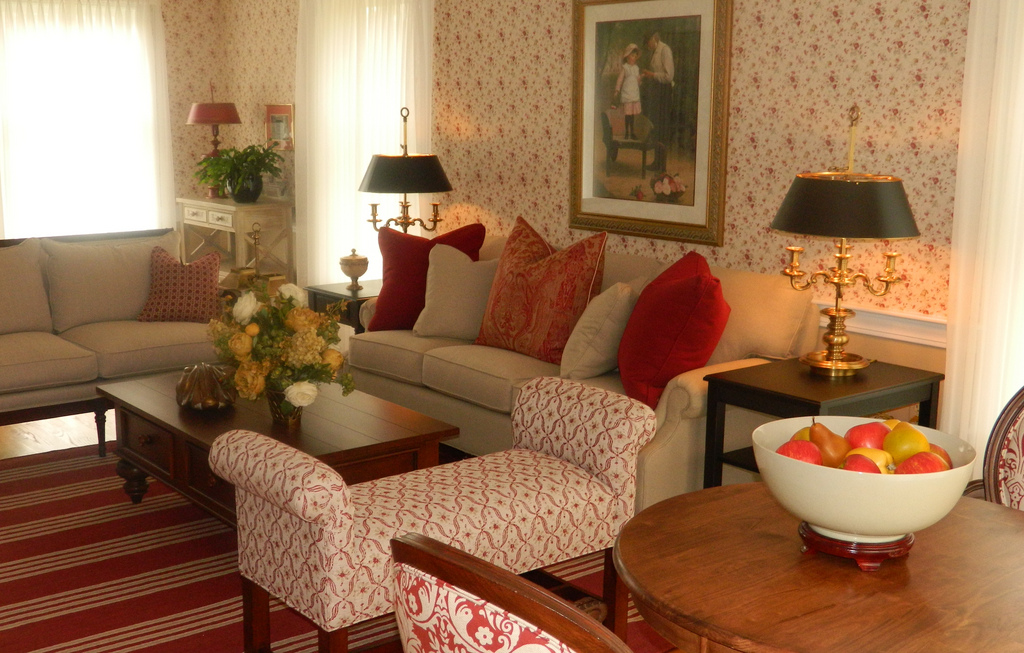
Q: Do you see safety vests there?
A: No, there are no safety vests.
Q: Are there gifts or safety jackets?
A: No, there are no safety jackets or gifts.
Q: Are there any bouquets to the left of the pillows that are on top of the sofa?
A: Yes, there is a bouquet to the left of the pillows.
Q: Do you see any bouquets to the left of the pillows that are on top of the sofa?
A: Yes, there is a bouquet to the left of the pillows.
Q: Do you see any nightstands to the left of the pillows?
A: No, there is a bouquet to the left of the pillows.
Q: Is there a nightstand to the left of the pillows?
A: No, there is a bouquet to the left of the pillows.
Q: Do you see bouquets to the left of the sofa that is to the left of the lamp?
A: Yes, there is a bouquet to the left of the sofa.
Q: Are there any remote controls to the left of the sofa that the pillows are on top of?
A: No, there is a bouquet to the left of the sofa.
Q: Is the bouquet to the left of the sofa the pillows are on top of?
A: Yes, the bouquet is to the left of the sofa.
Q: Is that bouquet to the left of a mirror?
A: No, the bouquet is to the left of the sofa.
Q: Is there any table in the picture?
A: Yes, there is a table.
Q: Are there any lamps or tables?
A: Yes, there is a table.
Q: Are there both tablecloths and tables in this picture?
A: No, there is a table but no tablecloths.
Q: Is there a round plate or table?
A: Yes, there is a round table.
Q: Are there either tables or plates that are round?
A: Yes, the table is round.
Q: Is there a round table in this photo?
A: Yes, there is a round table.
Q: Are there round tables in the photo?
A: Yes, there is a round table.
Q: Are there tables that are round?
A: Yes, there is a table that is round.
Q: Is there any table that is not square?
A: Yes, there is a round table.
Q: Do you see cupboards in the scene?
A: No, there are no cupboards.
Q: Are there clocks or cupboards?
A: No, there are no cupboards or clocks.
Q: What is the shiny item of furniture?
A: The piece of furniture is a table.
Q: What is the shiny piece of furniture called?
A: The piece of furniture is a table.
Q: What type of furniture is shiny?
A: The furniture is a table.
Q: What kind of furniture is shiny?
A: The furniture is a table.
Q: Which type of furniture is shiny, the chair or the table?
A: The table is shiny.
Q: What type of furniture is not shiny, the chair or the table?
A: The chair is not shiny.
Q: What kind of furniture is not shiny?
A: The furniture is a chair.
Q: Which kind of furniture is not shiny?
A: The furniture is a chair.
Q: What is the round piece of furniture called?
A: The piece of furniture is a table.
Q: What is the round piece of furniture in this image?
A: The piece of furniture is a table.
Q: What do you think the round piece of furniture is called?
A: The piece of furniture is a table.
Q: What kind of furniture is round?
A: The furniture is a table.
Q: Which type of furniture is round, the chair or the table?
A: The table is round.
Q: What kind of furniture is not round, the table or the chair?
A: The chair is not round.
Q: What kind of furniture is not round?
A: The furniture is a chair.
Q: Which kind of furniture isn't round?
A: The furniture is a chair.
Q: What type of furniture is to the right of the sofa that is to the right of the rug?
A: The piece of furniture is a table.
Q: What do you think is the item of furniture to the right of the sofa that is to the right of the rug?
A: The piece of furniture is a table.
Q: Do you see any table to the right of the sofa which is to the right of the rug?
A: Yes, there is a table to the right of the sofa.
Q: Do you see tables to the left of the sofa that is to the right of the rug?
A: No, the table is to the right of the sofa.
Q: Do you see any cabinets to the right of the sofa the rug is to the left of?
A: No, there is a table to the right of the sofa.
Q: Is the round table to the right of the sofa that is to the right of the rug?
A: Yes, the table is to the right of the sofa.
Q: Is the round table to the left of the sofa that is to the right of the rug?
A: No, the table is to the right of the sofa.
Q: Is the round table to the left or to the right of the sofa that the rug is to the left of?
A: The table is to the right of the sofa.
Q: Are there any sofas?
A: Yes, there is a sofa.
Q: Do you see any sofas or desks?
A: Yes, there is a sofa.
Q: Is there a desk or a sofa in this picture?
A: Yes, there is a sofa.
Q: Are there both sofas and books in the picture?
A: No, there is a sofa but no books.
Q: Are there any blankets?
A: No, there are no blankets.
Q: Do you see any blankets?
A: No, there are no blankets.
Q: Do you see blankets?
A: No, there are no blankets.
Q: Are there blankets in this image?
A: No, there are no blankets.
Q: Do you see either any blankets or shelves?
A: No, there are no blankets or shelves.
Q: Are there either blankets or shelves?
A: No, there are no blankets or shelves.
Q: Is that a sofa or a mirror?
A: That is a sofa.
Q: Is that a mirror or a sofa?
A: That is a sofa.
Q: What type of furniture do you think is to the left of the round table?
A: The piece of furniture is a sofa.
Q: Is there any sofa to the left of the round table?
A: Yes, there is a sofa to the left of the table.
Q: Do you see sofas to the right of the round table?
A: No, the sofa is to the left of the table.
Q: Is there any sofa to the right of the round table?
A: No, the sofa is to the left of the table.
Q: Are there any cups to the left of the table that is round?
A: No, there is a sofa to the left of the table.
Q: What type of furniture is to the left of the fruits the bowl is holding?
A: The piece of furniture is a sofa.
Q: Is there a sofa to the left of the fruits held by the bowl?
A: Yes, there is a sofa to the left of the fruits.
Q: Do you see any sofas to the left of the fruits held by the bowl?
A: Yes, there is a sofa to the left of the fruits.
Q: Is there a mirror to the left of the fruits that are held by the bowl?
A: No, there is a sofa to the left of the fruits.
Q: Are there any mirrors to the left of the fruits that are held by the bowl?
A: No, there is a sofa to the left of the fruits.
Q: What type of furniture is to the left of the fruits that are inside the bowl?
A: The piece of furniture is a sofa.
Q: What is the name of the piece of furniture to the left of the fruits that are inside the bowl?
A: The piece of furniture is a sofa.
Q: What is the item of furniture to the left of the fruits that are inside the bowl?
A: The piece of furniture is a sofa.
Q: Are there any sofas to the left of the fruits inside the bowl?
A: Yes, there is a sofa to the left of the fruits.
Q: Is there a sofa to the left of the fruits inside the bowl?
A: Yes, there is a sofa to the left of the fruits.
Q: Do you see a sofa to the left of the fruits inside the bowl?
A: Yes, there is a sofa to the left of the fruits.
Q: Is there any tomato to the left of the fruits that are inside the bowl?
A: No, there is a sofa to the left of the fruits.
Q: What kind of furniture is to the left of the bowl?
A: The piece of furniture is a sofa.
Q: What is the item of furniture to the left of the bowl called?
A: The piece of furniture is a sofa.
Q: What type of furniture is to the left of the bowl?
A: The piece of furniture is a sofa.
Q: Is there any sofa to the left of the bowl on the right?
A: Yes, there is a sofa to the left of the bowl.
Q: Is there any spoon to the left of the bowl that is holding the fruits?
A: No, there is a sofa to the left of the bowl.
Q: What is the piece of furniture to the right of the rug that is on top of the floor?
A: The piece of furniture is a sofa.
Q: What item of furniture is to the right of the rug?
A: The piece of furniture is a sofa.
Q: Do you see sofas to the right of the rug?
A: Yes, there is a sofa to the right of the rug.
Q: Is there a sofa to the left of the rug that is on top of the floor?
A: No, the sofa is to the right of the rug.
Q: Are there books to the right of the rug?
A: No, there is a sofa to the right of the rug.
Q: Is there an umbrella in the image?
A: No, there are no umbrellas.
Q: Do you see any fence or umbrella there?
A: No, there are no umbrellas or fences.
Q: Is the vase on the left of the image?
A: Yes, the vase is on the left of the image.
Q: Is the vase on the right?
A: No, the vase is on the left of the image.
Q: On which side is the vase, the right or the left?
A: The vase is on the left of the image.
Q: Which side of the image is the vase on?
A: The vase is on the left of the image.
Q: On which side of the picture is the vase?
A: The vase is on the left of the image.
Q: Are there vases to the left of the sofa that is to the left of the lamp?
A: Yes, there is a vase to the left of the sofa.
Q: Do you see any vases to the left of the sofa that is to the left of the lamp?
A: Yes, there is a vase to the left of the sofa.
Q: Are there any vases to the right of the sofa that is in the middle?
A: No, the vase is to the left of the sofa.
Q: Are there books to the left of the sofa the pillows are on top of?
A: No, there is a vase to the left of the sofa.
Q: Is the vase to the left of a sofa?
A: Yes, the vase is to the left of a sofa.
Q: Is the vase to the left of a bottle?
A: No, the vase is to the left of a sofa.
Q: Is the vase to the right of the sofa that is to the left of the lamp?
A: No, the vase is to the left of the sofa.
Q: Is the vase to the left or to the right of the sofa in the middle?
A: The vase is to the left of the sofa.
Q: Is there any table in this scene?
A: Yes, there is a table.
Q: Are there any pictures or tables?
A: Yes, there is a table.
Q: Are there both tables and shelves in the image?
A: No, there is a table but no shelves.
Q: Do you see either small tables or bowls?
A: Yes, there is a small table.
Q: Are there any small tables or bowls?
A: Yes, there is a small table.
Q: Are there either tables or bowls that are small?
A: Yes, the table is small.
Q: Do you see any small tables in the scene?
A: Yes, there is a small table.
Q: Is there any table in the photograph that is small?
A: Yes, there is a table that is small.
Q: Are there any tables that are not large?
A: Yes, there is a small table.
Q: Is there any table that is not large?
A: Yes, there is a small table.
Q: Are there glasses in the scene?
A: No, there are no glasses.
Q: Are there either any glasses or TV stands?
A: No, there are no glasses or TV stands.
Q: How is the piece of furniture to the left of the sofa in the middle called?
A: The piece of furniture is a table.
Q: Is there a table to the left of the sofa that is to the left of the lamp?
A: Yes, there is a table to the left of the sofa.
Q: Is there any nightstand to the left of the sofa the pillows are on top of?
A: No, there is a table to the left of the sofa.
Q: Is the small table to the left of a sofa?
A: Yes, the table is to the left of a sofa.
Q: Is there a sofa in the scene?
A: Yes, there is a sofa.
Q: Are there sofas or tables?
A: Yes, there is a sofa.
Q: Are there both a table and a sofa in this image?
A: Yes, there are both a sofa and a table.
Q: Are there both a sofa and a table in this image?
A: Yes, there are both a sofa and a table.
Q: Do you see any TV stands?
A: No, there are no TV stands.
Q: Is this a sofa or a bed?
A: This is a sofa.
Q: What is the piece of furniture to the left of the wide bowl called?
A: The piece of furniture is a sofa.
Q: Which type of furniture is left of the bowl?
A: The piece of furniture is a sofa.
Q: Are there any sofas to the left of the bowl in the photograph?
A: Yes, there is a sofa to the left of the bowl.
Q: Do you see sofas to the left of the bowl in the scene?
A: Yes, there is a sofa to the left of the bowl.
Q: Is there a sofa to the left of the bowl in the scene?
A: Yes, there is a sofa to the left of the bowl.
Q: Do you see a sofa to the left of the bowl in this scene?
A: Yes, there is a sofa to the left of the bowl.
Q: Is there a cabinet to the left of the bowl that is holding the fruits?
A: No, there is a sofa to the left of the bowl.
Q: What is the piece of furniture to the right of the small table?
A: The piece of furniture is a sofa.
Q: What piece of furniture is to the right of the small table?
A: The piece of furniture is a sofa.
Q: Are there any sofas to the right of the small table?
A: Yes, there is a sofa to the right of the table.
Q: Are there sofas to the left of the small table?
A: No, the sofa is to the right of the table.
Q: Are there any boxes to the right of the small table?
A: No, there is a sofa to the right of the table.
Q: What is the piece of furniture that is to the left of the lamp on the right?
A: The piece of furniture is a sofa.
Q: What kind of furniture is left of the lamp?
A: The piece of furniture is a sofa.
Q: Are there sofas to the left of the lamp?
A: Yes, there is a sofa to the left of the lamp.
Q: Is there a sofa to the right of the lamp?
A: No, the sofa is to the left of the lamp.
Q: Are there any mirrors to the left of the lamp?
A: No, there is a sofa to the left of the lamp.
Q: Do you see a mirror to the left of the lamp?
A: No, there is a sofa to the left of the lamp.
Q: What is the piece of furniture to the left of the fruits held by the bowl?
A: The piece of furniture is a sofa.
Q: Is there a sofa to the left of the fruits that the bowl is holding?
A: Yes, there is a sofa to the left of the fruits.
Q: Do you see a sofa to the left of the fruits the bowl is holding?
A: Yes, there is a sofa to the left of the fruits.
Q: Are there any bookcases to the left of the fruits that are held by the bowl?
A: No, there is a sofa to the left of the fruits.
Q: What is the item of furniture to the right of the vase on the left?
A: The piece of furniture is a sofa.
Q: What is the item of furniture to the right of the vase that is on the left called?
A: The piece of furniture is a sofa.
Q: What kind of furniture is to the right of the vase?
A: The piece of furniture is a sofa.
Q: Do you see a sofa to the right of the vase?
A: Yes, there is a sofa to the right of the vase.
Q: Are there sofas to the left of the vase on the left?
A: No, the sofa is to the right of the vase.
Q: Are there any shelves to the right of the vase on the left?
A: No, there is a sofa to the right of the vase.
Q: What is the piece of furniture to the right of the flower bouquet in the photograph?
A: The piece of furniture is a sofa.